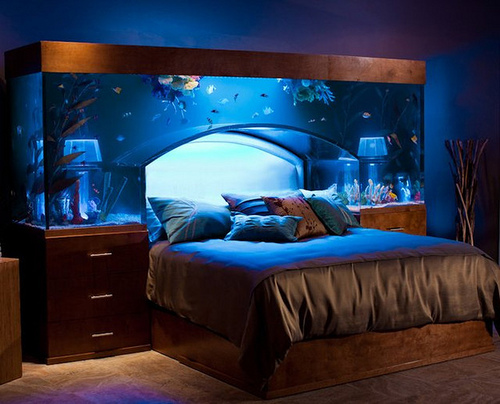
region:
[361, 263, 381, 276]
part of a bed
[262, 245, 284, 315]
edge of a bed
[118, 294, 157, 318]
part of a drawer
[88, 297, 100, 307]
part of a table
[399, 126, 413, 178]
part of a mirror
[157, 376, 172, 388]
part of a floor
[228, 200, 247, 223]
part of a pillow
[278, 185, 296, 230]
edge of a pillow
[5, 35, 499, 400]
an aquarium and bed on display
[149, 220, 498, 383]
a dark brown comforter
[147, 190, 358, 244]
several multi colored pillows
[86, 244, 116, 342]
three silver drawer pulls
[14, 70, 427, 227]
fish swimming in aquarium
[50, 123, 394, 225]
two lamps in aquarium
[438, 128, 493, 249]
a wooden stick decoration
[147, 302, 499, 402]
a brown wooden bed frame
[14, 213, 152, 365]
drawers are dark brown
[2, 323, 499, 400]
carpet is brown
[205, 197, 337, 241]
a pile of pillows on a bed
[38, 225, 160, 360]
a set of dresser drawers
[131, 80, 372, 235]
a fish tank over a bed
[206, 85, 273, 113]
fish in a fish tank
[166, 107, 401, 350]
a bed under a fish tank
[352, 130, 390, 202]
a lamp in a fish tank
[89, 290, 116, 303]
a handle to a dresser drawer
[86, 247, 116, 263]
a handle to a dresser drawer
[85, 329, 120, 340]
a handle to a dresser drawer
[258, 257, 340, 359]
a bedspread on a bed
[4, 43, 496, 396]
Bed set with an aquarium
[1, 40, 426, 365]
Dresser with an aquarium on top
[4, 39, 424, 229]
Aquarium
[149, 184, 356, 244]
Set of pillows on the bed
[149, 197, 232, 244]
Pillow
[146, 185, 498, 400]
Bed beneath the aquarium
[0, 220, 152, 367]
Set of drawers on the bottom of the aquarium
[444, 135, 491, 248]
Tree branches with out any leaves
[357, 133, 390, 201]
Lamp used to provide light to the aquarium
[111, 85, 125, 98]
Small orange fish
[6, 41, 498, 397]
bed with unique headboard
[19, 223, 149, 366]
wooden nightstand on left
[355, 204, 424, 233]
wooden nightstand on right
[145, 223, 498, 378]
brown satin bedspread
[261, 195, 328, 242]
brown satin embroidered throw pillow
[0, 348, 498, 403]
soft light brown carpeting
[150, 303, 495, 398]
solid wooden stained bedframe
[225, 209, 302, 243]
long rectangle throw pillow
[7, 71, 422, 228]
unique headboard is illuminated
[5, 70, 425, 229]
unique headboard is water-filled